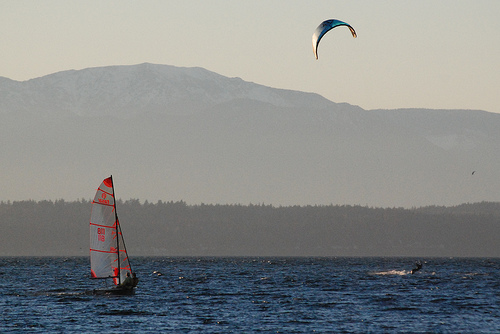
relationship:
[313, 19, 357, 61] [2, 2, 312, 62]
kite in sky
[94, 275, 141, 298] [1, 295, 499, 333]
boat in water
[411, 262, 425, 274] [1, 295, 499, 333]
man in water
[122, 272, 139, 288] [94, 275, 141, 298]
people are on boat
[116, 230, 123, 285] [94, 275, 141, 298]
mast attached to boat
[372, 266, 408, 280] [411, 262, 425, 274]
wake left of man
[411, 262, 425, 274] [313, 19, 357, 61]
man using kite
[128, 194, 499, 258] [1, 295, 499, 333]
trees are behind water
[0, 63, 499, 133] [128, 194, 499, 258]
mountains are behind trees